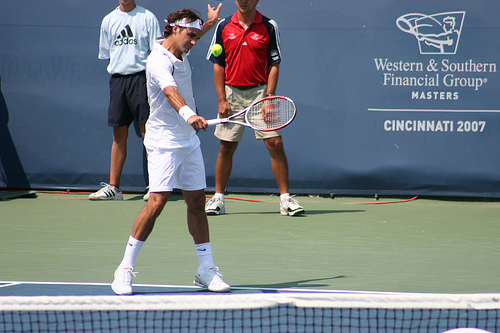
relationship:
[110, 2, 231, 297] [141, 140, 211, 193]
male/tennis player has white shorts